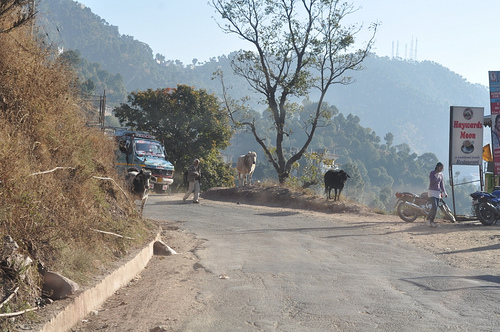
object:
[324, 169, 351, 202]
cow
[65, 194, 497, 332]
road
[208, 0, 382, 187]
tree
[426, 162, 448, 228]
man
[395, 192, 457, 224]
motorcycle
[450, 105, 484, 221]
sign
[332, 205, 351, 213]
rock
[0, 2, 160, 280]
hillside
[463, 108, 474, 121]
mark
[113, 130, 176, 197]
truck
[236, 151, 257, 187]
calf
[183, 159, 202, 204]
man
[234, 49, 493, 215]
hill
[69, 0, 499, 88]
sky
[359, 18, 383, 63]
twig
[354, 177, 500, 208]
hillside